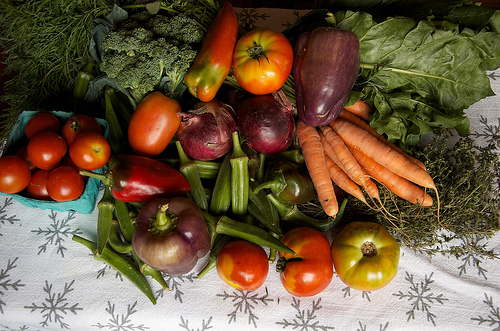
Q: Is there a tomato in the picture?
A: Yes, there is a tomato.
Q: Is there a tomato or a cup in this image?
A: Yes, there is a tomato.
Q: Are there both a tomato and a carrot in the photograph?
A: Yes, there are both a tomato and a carrot.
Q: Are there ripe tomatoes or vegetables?
A: Yes, there is a ripe tomato.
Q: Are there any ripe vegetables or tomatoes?
A: Yes, there is a ripe tomato.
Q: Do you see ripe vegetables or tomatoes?
A: Yes, there is a ripe tomato.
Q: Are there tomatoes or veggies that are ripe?
A: Yes, the tomato is ripe.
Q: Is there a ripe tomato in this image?
A: Yes, there is a ripe tomato.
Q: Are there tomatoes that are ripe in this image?
A: Yes, there is a ripe tomato.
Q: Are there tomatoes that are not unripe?
A: Yes, there is an ripe tomato.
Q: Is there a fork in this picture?
A: No, there are no forks.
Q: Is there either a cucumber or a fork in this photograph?
A: No, there are no forks or cucumbers.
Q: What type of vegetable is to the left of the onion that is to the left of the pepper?
A: The vegetable is a tomato.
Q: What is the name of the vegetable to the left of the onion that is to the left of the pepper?
A: The vegetable is a tomato.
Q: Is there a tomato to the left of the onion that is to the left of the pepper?
A: Yes, there is a tomato to the left of the onion.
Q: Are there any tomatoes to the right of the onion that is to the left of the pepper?
A: No, the tomato is to the left of the onion.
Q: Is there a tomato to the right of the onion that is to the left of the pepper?
A: No, the tomato is to the left of the onion.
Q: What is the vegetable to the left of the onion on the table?
A: The vegetable is a tomato.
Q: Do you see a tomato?
A: Yes, there is a tomato.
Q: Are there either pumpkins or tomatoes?
A: Yes, there is a tomato.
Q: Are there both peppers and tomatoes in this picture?
A: Yes, there are both a tomato and a pepper.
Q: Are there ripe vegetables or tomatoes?
A: Yes, there is a ripe tomato.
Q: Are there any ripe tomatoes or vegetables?
A: Yes, there is a ripe tomato.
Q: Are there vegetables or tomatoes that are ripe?
A: Yes, the tomato is ripe.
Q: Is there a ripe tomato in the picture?
A: Yes, there is a ripe tomato.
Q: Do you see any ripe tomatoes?
A: Yes, there is a ripe tomato.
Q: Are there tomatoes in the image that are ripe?
A: Yes, there is a tomato that is ripe.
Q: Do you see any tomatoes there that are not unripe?
A: Yes, there is an ripe tomato.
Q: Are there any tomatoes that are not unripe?
A: Yes, there is an ripe tomato.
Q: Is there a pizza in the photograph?
A: No, there are no pizzas.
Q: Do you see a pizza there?
A: No, there are no pizzas.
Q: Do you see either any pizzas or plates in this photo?
A: No, there are no pizzas or plates.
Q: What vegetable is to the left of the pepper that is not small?
A: The vegetable is a tomato.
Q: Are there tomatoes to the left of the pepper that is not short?
A: Yes, there is a tomato to the left of the pepper.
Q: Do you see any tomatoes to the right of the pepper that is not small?
A: No, the tomato is to the left of the pepper.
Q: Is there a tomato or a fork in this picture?
A: Yes, there is a tomato.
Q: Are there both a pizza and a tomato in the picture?
A: No, there is a tomato but no pizzas.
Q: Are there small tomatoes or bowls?
A: Yes, there is a small tomato.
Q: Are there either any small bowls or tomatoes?
A: Yes, there is a small tomato.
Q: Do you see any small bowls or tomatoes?
A: Yes, there is a small tomato.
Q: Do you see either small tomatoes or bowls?
A: Yes, there is a small tomato.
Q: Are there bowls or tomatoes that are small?
A: Yes, the tomato is small.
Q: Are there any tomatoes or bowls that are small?
A: Yes, the tomato is small.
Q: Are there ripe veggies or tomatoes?
A: Yes, there is a ripe tomato.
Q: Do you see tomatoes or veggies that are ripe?
A: Yes, the tomato is ripe.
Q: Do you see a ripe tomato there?
A: Yes, there is a ripe tomato.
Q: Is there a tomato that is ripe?
A: Yes, there is a tomato that is ripe.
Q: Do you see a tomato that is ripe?
A: Yes, there is a tomato that is ripe.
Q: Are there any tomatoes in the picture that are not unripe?
A: Yes, there is an ripe tomato.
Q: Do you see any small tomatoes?
A: Yes, there is a small tomato.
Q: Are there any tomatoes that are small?
A: Yes, there is a tomato that is small.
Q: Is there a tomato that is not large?
A: Yes, there is a small tomato.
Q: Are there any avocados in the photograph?
A: No, there are no avocados.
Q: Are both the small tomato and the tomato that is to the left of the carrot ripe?
A: Yes, both the tomato and the tomato are ripe.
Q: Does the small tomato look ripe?
A: Yes, the tomato is ripe.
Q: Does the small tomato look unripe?
A: No, the tomato is ripe.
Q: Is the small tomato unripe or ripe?
A: The tomato is ripe.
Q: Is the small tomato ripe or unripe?
A: The tomato is ripe.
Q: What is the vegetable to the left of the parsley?
A: The vegetable is a tomato.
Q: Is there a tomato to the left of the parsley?
A: Yes, there is a tomato to the left of the parsley.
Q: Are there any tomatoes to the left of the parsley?
A: Yes, there is a tomato to the left of the parsley.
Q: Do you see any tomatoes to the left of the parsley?
A: Yes, there is a tomato to the left of the parsley.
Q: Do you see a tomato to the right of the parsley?
A: No, the tomato is to the left of the parsley.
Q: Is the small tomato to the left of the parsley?
A: Yes, the tomato is to the left of the parsley.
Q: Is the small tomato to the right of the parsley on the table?
A: No, the tomato is to the left of the parsley.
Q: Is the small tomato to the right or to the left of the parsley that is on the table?
A: The tomato is to the left of the parsley.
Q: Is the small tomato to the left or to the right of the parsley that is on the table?
A: The tomato is to the left of the parsley.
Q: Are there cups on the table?
A: No, there is a tomato on the table.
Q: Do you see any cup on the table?
A: No, there is a tomato on the table.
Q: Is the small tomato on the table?
A: Yes, the tomato is on the table.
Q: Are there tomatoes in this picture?
A: Yes, there is a tomato.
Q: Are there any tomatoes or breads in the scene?
A: Yes, there is a tomato.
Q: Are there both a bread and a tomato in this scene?
A: No, there is a tomato but no breads.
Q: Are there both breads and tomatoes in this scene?
A: No, there is a tomato but no breads.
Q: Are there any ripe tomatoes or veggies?
A: Yes, there is a ripe tomato.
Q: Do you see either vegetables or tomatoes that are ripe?
A: Yes, the tomato is ripe.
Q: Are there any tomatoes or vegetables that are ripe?
A: Yes, the tomato is ripe.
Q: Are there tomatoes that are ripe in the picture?
A: Yes, there is a ripe tomato.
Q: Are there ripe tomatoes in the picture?
A: Yes, there is a ripe tomato.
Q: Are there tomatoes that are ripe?
A: Yes, there is a tomato that is ripe.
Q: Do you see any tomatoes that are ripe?
A: Yes, there is a tomato that is ripe.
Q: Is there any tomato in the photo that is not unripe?
A: Yes, there is an ripe tomato.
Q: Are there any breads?
A: No, there are no breads.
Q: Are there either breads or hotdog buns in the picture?
A: No, there are no breads or hotdog buns.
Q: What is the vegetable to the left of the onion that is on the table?
A: The vegetable is a tomato.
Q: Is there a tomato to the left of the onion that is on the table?
A: Yes, there is a tomato to the left of the onion.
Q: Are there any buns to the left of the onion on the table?
A: No, there is a tomato to the left of the onion.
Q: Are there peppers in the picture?
A: Yes, there is a pepper.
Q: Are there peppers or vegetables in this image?
A: Yes, there is a pepper.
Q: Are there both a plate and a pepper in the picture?
A: No, there is a pepper but no plates.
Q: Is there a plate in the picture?
A: No, there are no plates.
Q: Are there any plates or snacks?
A: No, there are no plates or snacks.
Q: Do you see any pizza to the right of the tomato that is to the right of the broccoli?
A: No, there is a pepper to the right of the tomato.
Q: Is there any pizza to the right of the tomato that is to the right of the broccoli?
A: No, there is a pepper to the right of the tomato.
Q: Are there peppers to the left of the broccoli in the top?
A: No, the pepper is to the right of the broccoli.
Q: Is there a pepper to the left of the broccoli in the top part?
A: No, the pepper is to the right of the broccoli.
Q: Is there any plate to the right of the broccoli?
A: No, there is a pepper to the right of the broccoli.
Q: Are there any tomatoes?
A: Yes, there are tomatoes.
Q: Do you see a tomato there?
A: Yes, there are tomatoes.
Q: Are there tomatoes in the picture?
A: Yes, there are tomatoes.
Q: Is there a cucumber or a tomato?
A: Yes, there are tomatoes.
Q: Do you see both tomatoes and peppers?
A: Yes, there are both tomatoes and a pepper.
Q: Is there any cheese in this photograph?
A: No, there is no cheese.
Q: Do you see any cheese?
A: No, there is no cheese.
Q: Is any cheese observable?
A: No, there is no cheese.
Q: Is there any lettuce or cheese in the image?
A: No, there are no cheese or lettuce.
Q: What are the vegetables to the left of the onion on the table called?
A: The vegetables are tomatoes.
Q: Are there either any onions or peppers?
A: Yes, there is a pepper.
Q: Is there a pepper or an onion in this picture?
A: Yes, there is a pepper.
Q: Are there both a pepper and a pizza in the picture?
A: No, there is a pepper but no pizzas.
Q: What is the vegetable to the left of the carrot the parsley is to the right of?
A: The vegetable is a pepper.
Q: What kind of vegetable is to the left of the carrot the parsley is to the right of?
A: The vegetable is a pepper.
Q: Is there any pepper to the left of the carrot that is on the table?
A: Yes, there is a pepper to the left of the carrot.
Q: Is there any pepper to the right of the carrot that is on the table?
A: No, the pepper is to the left of the carrot.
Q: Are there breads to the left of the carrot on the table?
A: No, there is a pepper to the left of the carrot.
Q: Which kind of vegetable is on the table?
A: The vegetable is a pepper.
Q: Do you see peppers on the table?
A: Yes, there is a pepper on the table.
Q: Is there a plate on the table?
A: No, there is a pepper on the table.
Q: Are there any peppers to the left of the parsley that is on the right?
A: Yes, there is a pepper to the left of the parsley.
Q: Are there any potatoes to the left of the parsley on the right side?
A: No, there is a pepper to the left of the parsley.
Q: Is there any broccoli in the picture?
A: Yes, there is broccoli.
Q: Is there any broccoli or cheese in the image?
A: Yes, there is broccoli.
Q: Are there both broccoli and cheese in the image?
A: No, there is broccoli but no cheese.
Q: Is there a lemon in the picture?
A: No, there are no lemons.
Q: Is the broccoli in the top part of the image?
A: Yes, the broccoli is in the top of the image.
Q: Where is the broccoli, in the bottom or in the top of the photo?
A: The broccoli is in the top of the image.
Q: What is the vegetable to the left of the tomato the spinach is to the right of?
A: The vegetable is broccoli.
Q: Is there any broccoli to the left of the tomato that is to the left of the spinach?
A: Yes, there is broccoli to the left of the tomato.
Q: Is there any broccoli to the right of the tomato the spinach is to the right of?
A: No, the broccoli is to the left of the tomato.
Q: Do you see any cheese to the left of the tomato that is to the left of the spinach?
A: No, there is broccoli to the left of the tomato.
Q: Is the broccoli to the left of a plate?
A: No, the broccoli is to the left of the tomato.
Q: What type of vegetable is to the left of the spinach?
A: The vegetable is broccoli.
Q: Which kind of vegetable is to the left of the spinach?
A: The vegetable is broccoli.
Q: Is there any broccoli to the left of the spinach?
A: Yes, there is broccoli to the left of the spinach.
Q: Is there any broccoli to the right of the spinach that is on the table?
A: No, the broccoli is to the left of the spinach.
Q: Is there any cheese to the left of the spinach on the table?
A: No, there is broccoli to the left of the spinach.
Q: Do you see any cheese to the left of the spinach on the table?
A: No, there is broccoli to the left of the spinach.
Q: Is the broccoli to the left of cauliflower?
A: No, the broccoli is to the left of the spinach.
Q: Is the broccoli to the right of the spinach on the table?
A: No, the broccoli is to the left of the spinach.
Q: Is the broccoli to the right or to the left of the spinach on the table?
A: The broccoli is to the left of the spinach.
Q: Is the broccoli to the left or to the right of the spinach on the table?
A: The broccoli is to the left of the spinach.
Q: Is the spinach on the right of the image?
A: Yes, the spinach is on the right of the image.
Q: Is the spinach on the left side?
A: No, the spinach is on the right of the image.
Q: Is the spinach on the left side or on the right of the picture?
A: The spinach is on the right of the image.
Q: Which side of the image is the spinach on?
A: The spinach is on the right of the image.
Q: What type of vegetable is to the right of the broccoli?
A: The vegetable is spinach.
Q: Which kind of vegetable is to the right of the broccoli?
A: The vegetable is spinach.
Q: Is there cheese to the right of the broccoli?
A: No, there is spinach to the right of the broccoli.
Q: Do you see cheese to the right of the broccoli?
A: No, there is spinach to the right of the broccoli.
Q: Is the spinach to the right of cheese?
A: No, the spinach is to the right of the broccoli.